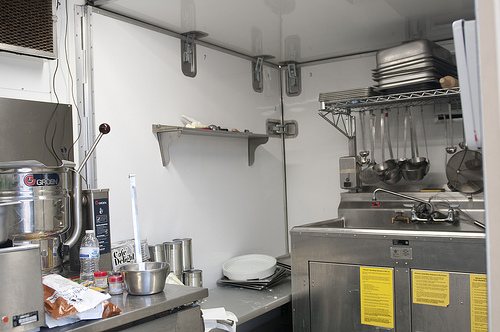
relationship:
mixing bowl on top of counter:
[120, 261, 170, 297] [41, 275, 209, 331]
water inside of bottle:
[79, 271, 96, 281] [77, 229, 101, 285]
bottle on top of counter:
[77, 229, 101, 285] [41, 275, 209, 331]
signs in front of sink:
[358, 266, 488, 331] [286, 215, 487, 238]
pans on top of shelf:
[370, 36, 457, 92] [318, 85, 460, 138]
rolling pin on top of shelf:
[438, 72, 458, 94] [318, 85, 460, 138]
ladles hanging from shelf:
[352, 100, 467, 185] [318, 85, 460, 138]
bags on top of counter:
[42, 271, 121, 329] [41, 275, 209, 331]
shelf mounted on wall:
[150, 119, 270, 167] [0, 0, 289, 291]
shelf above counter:
[150, 119, 270, 167] [192, 252, 291, 331]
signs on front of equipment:
[358, 266, 488, 331] [288, 185, 488, 331]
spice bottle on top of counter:
[108, 272, 125, 295] [41, 275, 209, 331]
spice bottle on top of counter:
[93, 267, 107, 289] [41, 275, 209, 331]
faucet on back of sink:
[370, 187, 458, 222] [286, 215, 487, 238]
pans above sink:
[370, 36, 457, 92] [286, 215, 487, 238]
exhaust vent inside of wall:
[0, 0, 60, 58] [0, 0, 289, 291]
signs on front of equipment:
[358, 266, 395, 329] [288, 185, 488, 331]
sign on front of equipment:
[412, 268, 450, 307] [288, 185, 488, 331]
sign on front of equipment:
[468, 272, 485, 331] [288, 185, 488, 331]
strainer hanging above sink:
[444, 146, 483, 197] [286, 215, 487, 238]